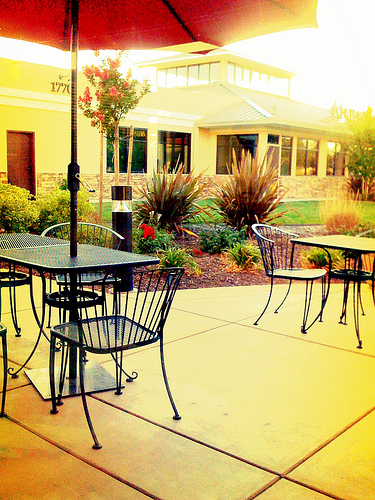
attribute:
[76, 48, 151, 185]
tree — green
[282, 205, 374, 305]
table — black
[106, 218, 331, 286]
mulch — red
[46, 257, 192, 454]
chair — black, metal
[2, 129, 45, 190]
door — brown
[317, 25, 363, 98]
sky — clear, white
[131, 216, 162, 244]
flowers — red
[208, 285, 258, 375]
sidewalk — cracked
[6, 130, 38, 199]
door — brown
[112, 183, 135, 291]
pole — black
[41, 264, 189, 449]
chairs — black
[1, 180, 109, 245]
bush — green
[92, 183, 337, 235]
grass — green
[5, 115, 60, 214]
door — red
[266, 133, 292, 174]
window — glass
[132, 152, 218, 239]
plant — tall, glassy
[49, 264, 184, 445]
chairs — metal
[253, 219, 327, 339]
chairs — metal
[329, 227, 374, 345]
chairs — metal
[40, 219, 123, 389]
chairs — metal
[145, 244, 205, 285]
plant — short, grassy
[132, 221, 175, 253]
plant — short, grassy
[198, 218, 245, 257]
plant — short, grassy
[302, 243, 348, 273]
plant — short, grassy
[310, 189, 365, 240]
plant — short, grassy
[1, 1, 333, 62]
unbrella — red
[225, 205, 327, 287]
chair — green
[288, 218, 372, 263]
table — square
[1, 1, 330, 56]
umbrella — open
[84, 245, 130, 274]
part — small